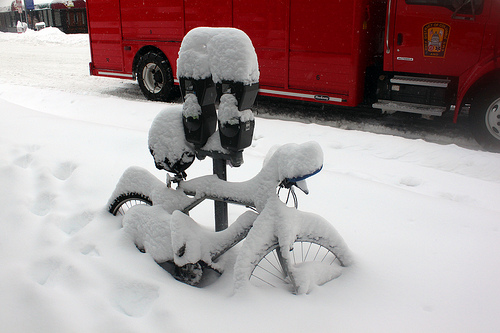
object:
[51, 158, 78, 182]
foot prints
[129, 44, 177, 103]
tire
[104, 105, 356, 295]
bicycle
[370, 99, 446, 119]
silver steps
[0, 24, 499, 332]
snow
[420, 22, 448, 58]
emblem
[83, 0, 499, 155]
red truck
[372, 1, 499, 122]
truck cab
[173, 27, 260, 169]
meter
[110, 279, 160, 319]
footprints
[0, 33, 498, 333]
road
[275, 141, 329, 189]
handle bars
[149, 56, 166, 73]
chains